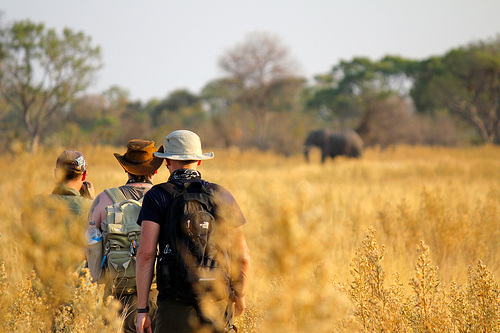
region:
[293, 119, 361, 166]
elephant on plain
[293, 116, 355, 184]
gray elephant on plain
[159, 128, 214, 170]
man wearing tan hat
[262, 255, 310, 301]
long yellow grass on plain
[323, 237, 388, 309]
long yellow grass on plain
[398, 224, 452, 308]
long yellow grass on plain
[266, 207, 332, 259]
long yellow grass on plain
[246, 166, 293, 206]
long yellow grass on plain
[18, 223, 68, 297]
long yellow grass on plain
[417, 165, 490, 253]
long yellow grass on plain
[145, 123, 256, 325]
man wearing white hat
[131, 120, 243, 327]
man wearing black backpack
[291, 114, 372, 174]
blurry grey elephant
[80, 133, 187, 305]
man wearing brown hat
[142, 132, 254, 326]
man wearing black shirt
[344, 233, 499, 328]
tall yellow dried grass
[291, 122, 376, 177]
elephant standing in tall dry grass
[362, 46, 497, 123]
trees with green leaves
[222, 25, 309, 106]
tree with no leaves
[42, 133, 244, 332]
three men standing in grass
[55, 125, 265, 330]
Three people watch an elephant.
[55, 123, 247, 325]
Three people in a grassy field.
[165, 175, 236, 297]
A large black backpack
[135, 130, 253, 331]
A man carrying a large black backpack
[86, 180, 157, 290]
A light green backpack.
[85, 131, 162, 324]
A man carrying a light green backpack.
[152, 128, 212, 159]
A light cream colored hat.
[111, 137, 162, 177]
A dark brown hat on a man with a green backpack.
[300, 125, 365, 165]
A large grey elephant in the background.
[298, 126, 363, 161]
An elephant standing in a grassy field.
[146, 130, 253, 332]
A man with backpack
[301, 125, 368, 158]
this is an elephant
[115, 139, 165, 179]
Man wearing brown hat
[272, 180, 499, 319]
This is tall grass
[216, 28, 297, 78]
This is a tree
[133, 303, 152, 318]
This is a watch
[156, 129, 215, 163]
This is a white hat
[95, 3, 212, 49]
The sun is shining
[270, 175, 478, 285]
This grass is gold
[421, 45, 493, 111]
The leaves are green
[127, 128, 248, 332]
Man wearing beige hat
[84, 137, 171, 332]
Man wearing brown hat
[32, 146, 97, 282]
Man wearing brown cap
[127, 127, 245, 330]
Man wearing black backpack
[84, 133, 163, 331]
Man wearing light green backpack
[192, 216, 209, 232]
White THE NORTH FACE logo on black backpack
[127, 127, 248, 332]
Man wearing black watch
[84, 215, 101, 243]
Plastic water bottle in light green backpack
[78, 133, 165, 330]
Man has tattoo on shoulder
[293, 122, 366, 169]
Large elephant is standing